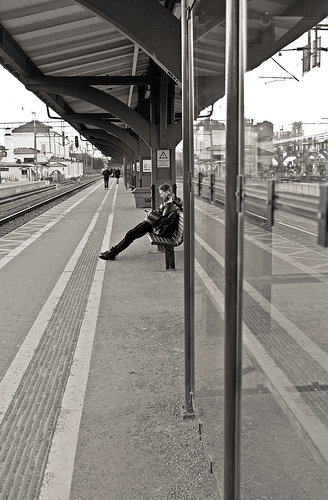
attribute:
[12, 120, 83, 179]
building — white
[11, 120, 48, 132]
roof — dark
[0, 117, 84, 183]
building — white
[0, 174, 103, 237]
train tracks — parallell, sets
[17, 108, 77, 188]
buildings — across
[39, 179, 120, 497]
line — parallel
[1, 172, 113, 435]
line — parallel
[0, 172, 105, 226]
tracks — going through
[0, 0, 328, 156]
roof — metal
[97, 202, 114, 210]
paint — fading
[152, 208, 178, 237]
backpack — black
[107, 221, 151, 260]
legs — stretched out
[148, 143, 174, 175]
sign — white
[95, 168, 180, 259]
woman — seated